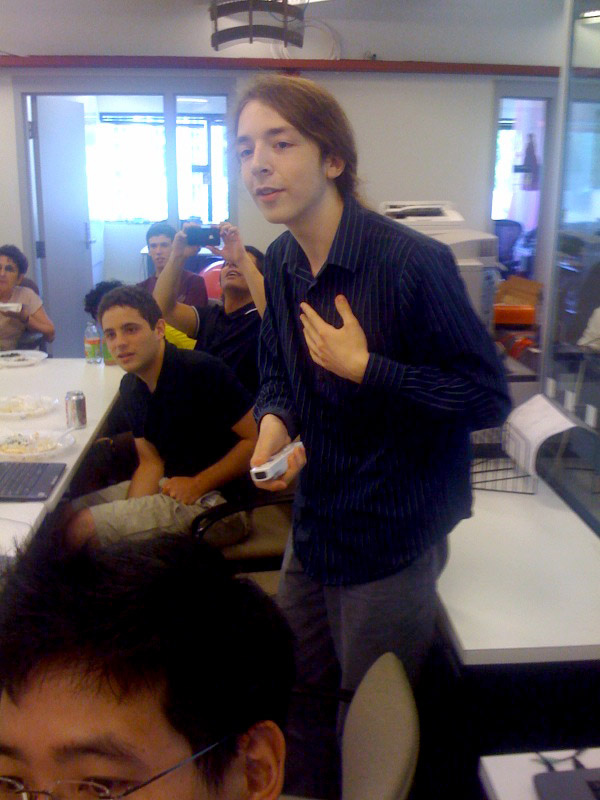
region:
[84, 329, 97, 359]
A bottle of water on a table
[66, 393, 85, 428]
A can of drink sitting on a table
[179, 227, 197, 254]
A hand holding a camera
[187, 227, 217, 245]
A camera held in the hands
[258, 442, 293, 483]
A hand holding a remote control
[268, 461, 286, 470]
A remote control held in the hand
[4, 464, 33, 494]
The key pad of a black lap top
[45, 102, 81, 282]
An open door on the far side of the room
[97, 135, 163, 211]
Light shining through the window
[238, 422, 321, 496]
this is a video game remote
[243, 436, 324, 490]
a video game console remote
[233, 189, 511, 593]
this is a blue button down shirt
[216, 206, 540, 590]
the shirt has stripes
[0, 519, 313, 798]
he is wearing glasses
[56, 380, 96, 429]
a silver soda can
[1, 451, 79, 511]
this is a keyboard and trackpad on a laptop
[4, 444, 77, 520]
a grey notebook computer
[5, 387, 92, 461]
plastic plates of food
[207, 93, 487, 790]
guy holding a Wii remote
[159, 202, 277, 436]
a guy taking a picture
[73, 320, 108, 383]
an empty Gatorade bottle on the table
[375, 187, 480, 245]
a printer against the wall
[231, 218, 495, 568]
a black pin striped shirt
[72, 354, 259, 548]
a guy in a black shirt and tan shorts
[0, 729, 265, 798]
glasses on his face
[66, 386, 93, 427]
a coke can on the table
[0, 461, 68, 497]
a keyboard to a laptop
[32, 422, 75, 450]
a white plastic fork on the plate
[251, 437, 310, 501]
a boy holding a white game controller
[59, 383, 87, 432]
a drink can on a table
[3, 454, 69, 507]
a black laptop on a table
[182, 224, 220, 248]
a black cell phone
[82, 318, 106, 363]
a glass drink bottle on a table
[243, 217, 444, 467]
a boy wearing a blue shirt with stripes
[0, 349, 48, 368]
a white plate on a table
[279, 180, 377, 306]
Blue collar of a shirt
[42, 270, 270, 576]
A guy is sitting down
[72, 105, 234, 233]
Bright daylight coming through window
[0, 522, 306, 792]
Black hair on a guy's head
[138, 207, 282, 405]
A guy is holding a cell phone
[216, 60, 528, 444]
A guy has his hand on his chest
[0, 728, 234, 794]
A pair of glasses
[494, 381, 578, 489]
A white piece of paper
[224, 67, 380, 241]
A man has long brown hair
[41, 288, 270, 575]
A person is sitting down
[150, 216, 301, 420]
A person is sitting down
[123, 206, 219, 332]
A person is sitting down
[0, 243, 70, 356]
A person is sitting down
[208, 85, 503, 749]
A person is standing up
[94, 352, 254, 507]
A piece of clothing.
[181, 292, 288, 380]
A piece of clothing.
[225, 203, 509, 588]
A piece of clothing.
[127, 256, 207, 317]
A piece of clothing.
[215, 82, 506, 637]
man wearing blue and black striped shirt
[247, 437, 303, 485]
white game controller man is holding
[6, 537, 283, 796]
man wearing eye glasses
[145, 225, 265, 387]
man holding up his phone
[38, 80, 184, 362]
open door in the background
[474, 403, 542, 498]
black wire basket on the table